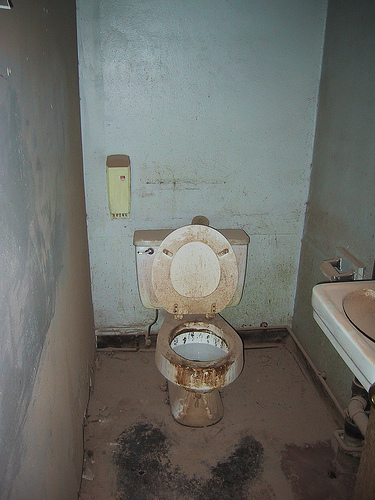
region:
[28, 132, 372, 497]
the bathroom is disgusting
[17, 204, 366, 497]
the bathroom is dirty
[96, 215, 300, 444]
the toilet should be white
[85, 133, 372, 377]
the walls are dirty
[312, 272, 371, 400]
the sink is dirty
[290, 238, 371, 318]
the toilet paper is gone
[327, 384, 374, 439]
the pipe is dusty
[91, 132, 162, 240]
air freshener on the wall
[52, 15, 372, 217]
the walls are gray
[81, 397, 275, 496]
the floor has black spots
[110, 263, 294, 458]
the toilet is untidy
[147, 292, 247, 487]
the toilet is untidy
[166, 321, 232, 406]
the toilet is untidy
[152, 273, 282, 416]
the toilet is very dirty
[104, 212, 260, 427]
the toilet is very dirty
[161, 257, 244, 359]
the toilet is very dirty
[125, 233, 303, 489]
the toilet is very dirty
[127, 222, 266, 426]
The toilet is a little dirty.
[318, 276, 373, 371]
The sink is dirty.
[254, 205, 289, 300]
The wall is dirty.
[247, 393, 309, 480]
The floor is dirty.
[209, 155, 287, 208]
The wall use to be blue.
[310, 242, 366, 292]
No toilet paper is in the holder.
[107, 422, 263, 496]
The floor has a black spot on it.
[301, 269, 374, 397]
The sink is white under the dirt.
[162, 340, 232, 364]
The water is clear.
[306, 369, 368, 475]
Pipes under the sink.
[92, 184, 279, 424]
a dirty bathroom toilet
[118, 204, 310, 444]
a bathroom toilet inside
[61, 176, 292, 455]
a public bathroom toilet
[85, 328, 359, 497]
a dirty bathroom floor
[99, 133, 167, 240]
a dispenser on teh wall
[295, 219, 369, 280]
a toilet paper holder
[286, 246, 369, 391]
a bathroom sink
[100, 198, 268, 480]
a bathroom toilet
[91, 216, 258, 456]
a white bathroom toilet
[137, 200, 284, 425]
a dirty white bathroom toilet